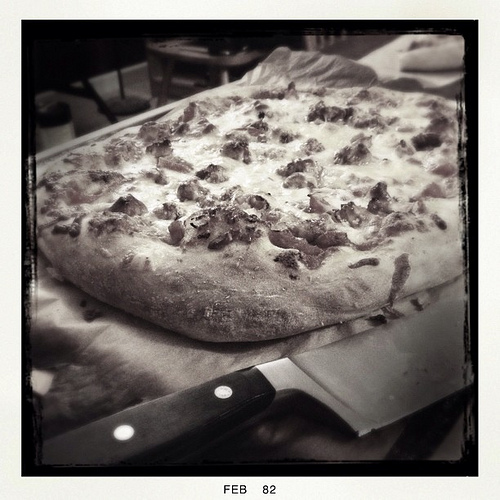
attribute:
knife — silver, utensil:
[31, 285, 469, 480]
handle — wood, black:
[30, 363, 280, 472]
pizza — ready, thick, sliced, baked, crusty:
[26, 79, 469, 348]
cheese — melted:
[234, 161, 277, 189]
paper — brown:
[231, 45, 384, 89]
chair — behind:
[145, 34, 282, 116]